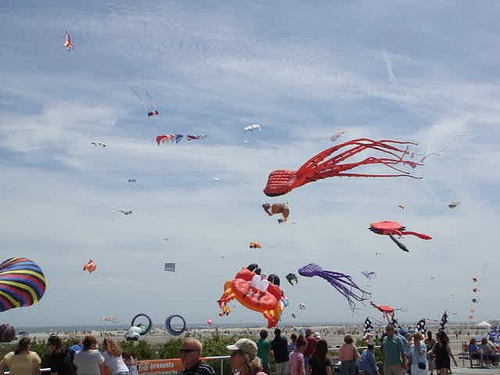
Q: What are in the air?
A: Kites.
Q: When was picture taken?
A: During daylight hours.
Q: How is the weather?
A: High clouds.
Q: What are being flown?
A: Kites.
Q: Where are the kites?
A: In the sky.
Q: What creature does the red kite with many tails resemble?
A: Squid.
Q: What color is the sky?
A: Blue and white.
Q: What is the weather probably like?
A: Windy.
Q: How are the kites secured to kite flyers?
A: With string.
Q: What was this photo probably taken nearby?
A: Beach.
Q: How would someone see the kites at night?
A: By using lights.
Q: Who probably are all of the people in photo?
A: Vacationers.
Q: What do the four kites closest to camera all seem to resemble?
A: Sea creatures.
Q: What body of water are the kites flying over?
A: Ocean.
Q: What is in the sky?
A: Kites.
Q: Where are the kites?
A: In the sky.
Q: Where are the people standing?
A: On the sand.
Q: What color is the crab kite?
A: Red.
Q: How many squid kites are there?
A: Two.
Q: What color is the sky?
A: Blue.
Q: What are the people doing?
A: Flying kites.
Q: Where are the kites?
A: In the sky.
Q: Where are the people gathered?
A: On the beach.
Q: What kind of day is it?
A: Windy.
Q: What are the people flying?
A: Kites.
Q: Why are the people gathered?
A: To fly kites.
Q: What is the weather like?
A: Cloudy.